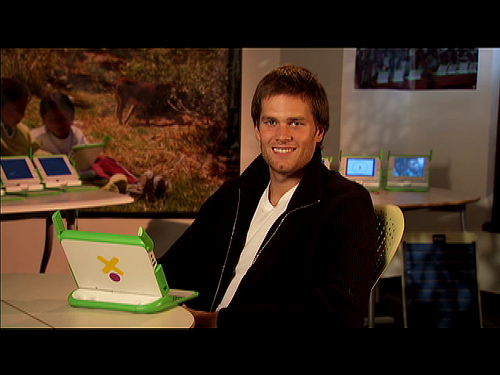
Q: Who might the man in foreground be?
A: Student.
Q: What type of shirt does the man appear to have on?
A: T-shirt.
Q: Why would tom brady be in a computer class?
A: To learn computer skills.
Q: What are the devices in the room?
A: Computers.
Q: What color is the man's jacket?
A: Black.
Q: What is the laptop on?
A: Table.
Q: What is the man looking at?
A: The camera.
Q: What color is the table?
A: White.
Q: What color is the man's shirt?
A: White.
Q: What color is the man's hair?
A: Brown.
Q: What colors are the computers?
A: White and green.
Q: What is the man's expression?
A: Smiling.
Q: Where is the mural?
A: On the wall.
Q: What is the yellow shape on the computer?
A: An x.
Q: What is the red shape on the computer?
A: A circle.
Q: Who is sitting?
A: Tom Brady.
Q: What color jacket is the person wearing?
A: Black.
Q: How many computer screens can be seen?
A: Four.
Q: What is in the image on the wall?
A: Children and animals.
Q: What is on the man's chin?
A: Dimple.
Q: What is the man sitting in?
A: A chair.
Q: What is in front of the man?
A: A computer.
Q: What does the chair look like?
A: White with holes.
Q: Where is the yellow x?
A: Back of computer.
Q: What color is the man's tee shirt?
A: White.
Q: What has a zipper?
A: Man's jacket.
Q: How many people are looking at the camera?
A: 1.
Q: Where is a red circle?
A: Under yellow X.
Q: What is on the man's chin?
A: Dimple.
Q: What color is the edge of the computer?
A: Green.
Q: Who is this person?
A: A man.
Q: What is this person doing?
A: Smiling.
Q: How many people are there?
A: One.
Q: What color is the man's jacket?
A: Black.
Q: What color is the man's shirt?
A: White.